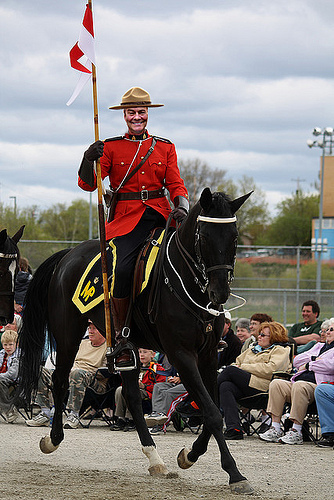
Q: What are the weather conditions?
A: It is overcast.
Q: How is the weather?
A: It is overcast.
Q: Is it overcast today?
A: Yes, it is overcast.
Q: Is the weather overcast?
A: Yes, it is overcast.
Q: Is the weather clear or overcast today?
A: It is overcast.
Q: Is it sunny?
A: No, it is overcast.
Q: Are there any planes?
A: No, there are no planes.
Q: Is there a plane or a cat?
A: No, there are no airplanes or cats.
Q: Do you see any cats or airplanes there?
A: No, there are no airplanes or cats.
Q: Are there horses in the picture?
A: Yes, there is a horse.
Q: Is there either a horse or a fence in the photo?
A: Yes, there is a horse.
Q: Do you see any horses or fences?
A: Yes, there is a horse.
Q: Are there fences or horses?
A: Yes, there is a horse.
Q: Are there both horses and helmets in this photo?
A: No, there is a horse but no helmets.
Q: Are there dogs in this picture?
A: No, there are no dogs.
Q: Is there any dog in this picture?
A: No, there are no dogs.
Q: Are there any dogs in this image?
A: No, there are no dogs.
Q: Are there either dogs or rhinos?
A: No, there are no dogs or rhinos.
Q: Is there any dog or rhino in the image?
A: No, there are no dogs or rhinos.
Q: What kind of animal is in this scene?
A: The animal is a horse.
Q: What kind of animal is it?
A: The animal is a horse.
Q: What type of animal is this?
A: This is a horse.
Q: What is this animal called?
A: This is a horse.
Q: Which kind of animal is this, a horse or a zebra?
A: This is a horse.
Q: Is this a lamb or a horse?
A: This is a horse.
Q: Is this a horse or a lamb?
A: This is a horse.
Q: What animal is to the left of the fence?
A: The animal is a horse.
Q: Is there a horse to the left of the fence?
A: Yes, there is a horse to the left of the fence.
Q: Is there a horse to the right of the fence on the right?
A: No, the horse is to the left of the fence.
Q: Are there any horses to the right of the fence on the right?
A: No, the horse is to the left of the fence.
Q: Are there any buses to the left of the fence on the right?
A: No, there is a horse to the left of the fence.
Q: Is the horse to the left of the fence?
A: Yes, the horse is to the left of the fence.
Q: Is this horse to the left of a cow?
A: No, the horse is to the left of the fence.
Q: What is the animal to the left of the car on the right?
A: The animal is a horse.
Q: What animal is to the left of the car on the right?
A: The animal is a horse.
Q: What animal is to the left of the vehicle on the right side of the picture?
A: The animal is a horse.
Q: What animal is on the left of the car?
A: The animal is a horse.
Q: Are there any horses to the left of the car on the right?
A: Yes, there is a horse to the left of the car.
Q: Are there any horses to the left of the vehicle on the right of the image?
A: Yes, there is a horse to the left of the car.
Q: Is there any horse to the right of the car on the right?
A: No, the horse is to the left of the car.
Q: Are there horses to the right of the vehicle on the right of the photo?
A: No, the horse is to the left of the car.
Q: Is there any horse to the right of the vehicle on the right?
A: No, the horse is to the left of the car.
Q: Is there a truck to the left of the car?
A: No, there is a horse to the left of the car.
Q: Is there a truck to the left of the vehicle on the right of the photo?
A: No, there is a horse to the left of the car.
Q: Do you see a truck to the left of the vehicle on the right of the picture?
A: No, there is a horse to the left of the car.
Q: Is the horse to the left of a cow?
A: No, the horse is to the left of the car.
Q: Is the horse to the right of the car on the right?
A: No, the horse is to the left of the car.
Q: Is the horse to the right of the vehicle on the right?
A: No, the horse is to the left of the car.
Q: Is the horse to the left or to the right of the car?
A: The horse is to the left of the car.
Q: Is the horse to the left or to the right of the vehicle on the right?
A: The horse is to the left of the car.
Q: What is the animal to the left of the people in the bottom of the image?
A: The animal is a horse.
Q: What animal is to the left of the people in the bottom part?
A: The animal is a horse.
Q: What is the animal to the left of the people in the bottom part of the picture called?
A: The animal is a horse.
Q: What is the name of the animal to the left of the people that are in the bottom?
A: The animal is a horse.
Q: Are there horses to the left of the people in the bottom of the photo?
A: Yes, there is a horse to the left of the people.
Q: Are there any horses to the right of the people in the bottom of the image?
A: No, the horse is to the left of the people.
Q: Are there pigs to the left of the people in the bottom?
A: No, there is a horse to the left of the people.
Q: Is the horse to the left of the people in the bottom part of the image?
A: Yes, the horse is to the left of the people.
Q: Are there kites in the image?
A: No, there are no kites.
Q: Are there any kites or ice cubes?
A: No, there are no kites or ice cubes.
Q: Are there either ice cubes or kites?
A: No, there are no kites or ice cubes.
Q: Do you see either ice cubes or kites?
A: No, there are no kites or ice cubes.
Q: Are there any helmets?
A: No, there are no helmets.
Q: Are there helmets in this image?
A: No, there are no helmets.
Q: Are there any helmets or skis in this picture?
A: No, there are no helmets or skis.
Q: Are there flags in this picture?
A: Yes, there is a flag.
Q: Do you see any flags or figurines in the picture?
A: Yes, there is a flag.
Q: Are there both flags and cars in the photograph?
A: Yes, there are both a flag and a car.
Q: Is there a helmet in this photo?
A: No, there are no helmets.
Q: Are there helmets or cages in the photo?
A: No, there are no helmets or cages.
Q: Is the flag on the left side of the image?
A: Yes, the flag is on the left of the image.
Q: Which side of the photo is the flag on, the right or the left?
A: The flag is on the left of the image.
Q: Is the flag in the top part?
A: Yes, the flag is in the top of the image.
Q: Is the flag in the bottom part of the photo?
A: No, the flag is in the top of the image.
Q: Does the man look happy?
A: Yes, the man is happy.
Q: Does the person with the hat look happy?
A: Yes, the man is happy.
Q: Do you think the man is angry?
A: No, the man is happy.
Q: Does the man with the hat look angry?
A: No, the man is happy.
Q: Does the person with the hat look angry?
A: No, the man is happy.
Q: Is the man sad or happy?
A: The man is happy.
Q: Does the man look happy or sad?
A: The man is happy.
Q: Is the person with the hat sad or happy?
A: The man is happy.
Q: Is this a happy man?
A: Yes, this is a happy man.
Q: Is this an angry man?
A: No, this is a happy man.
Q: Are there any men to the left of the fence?
A: Yes, there is a man to the left of the fence.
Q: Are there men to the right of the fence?
A: No, the man is to the left of the fence.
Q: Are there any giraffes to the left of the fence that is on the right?
A: No, there is a man to the left of the fence.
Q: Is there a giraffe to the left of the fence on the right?
A: No, there is a man to the left of the fence.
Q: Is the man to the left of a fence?
A: Yes, the man is to the left of a fence.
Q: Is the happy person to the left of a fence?
A: Yes, the man is to the left of a fence.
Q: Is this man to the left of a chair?
A: No, the man is to the left of a fence.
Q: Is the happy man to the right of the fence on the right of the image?
A: No, the man is to the left of the fence.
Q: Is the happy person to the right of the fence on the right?
A: No, the man is to the left of the fence.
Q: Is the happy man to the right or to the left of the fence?
A: The man is to the left of the fence.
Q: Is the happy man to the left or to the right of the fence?
A: The man is to the left of the fence.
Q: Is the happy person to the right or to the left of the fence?
A: The man is to the left of the fence.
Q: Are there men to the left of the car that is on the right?
A: Yes, there is a man to the left of the car.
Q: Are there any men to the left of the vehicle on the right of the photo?
A: Yes, there is a man to the left of the car.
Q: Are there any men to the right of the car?
A: No, the man is to the left of the car.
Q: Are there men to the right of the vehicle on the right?
A: No, the man is to the left of the car.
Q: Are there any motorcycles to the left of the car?
A: No, there is a man to the left of the car.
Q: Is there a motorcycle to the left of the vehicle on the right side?
A: No, there is a man to the left of the car.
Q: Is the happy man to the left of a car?
A: Yes, the man is to the left of a car.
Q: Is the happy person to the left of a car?
A: Yes, the man is to the left of a car.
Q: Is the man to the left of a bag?
A: No, the man is to the left of a car.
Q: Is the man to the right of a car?
A: No, the man is to the left of a car.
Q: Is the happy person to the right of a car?
A: No, the man is to the left of a car.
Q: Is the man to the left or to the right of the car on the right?
A: The man is to the left of the car.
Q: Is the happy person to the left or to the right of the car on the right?
A: The man is to the left of the car.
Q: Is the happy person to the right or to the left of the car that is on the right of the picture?
A: The man is to the left of the car.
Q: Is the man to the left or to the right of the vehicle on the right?
A: The man is to the left of the car.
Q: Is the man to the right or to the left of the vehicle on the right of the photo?
A: The man is to the left of the car.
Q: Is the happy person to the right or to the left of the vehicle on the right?
A: The man is to the left of the car.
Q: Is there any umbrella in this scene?
A: No, there are no umbrellas.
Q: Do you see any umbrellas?
A: No, there are no umbrellas.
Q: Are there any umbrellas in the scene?
A: No, there are no umbrellas.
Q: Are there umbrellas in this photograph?
A: No, there are no umbrellas.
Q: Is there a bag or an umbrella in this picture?
A: No, there are no umbrellas or bags.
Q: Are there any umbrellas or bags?
A: No, there are no umbrellas or bags.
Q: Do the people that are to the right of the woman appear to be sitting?
A: Yes, the people are sitting.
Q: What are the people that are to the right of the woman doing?
A: The people are sitting.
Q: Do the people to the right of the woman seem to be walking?
A: No, the people are sitting.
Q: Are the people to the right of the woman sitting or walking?
A: The people are sitting.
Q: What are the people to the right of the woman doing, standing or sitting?
A: The people are sitting.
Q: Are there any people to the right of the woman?
A: Yes, there are people to the right of the woman.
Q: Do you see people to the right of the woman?
A: Yes, there are people to the right of the woman.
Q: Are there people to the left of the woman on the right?
A: No, the people are to the right of the woman.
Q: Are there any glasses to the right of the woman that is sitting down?
A: No, there are people to the right of the woman.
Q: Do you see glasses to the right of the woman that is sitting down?
A: No, there are people to the right of the woman.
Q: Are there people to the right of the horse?
A: Yes, there are people to the right of the horse.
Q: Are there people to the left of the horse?
A: No, the people are to the right of the horse.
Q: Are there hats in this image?
A: Yes, there is a hat.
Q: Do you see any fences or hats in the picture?
A: Yes, there is a hat.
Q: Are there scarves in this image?
A: No, there are no scarves.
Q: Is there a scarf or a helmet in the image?
A: No, there are no scarves or helmets.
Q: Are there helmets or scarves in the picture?
A: No, there are no scarves or helmets.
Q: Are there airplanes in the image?
A: No, there are no airplanes.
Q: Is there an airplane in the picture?
A: No, there are no airplanes.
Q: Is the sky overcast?
A: Yes, the sky is overcast.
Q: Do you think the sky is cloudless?
A: No, the sky is overcast.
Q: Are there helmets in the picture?
A: No, there are no helmets.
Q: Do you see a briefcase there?
A: No, there are no briefcases.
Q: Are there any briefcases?
A: No, there are no briefcases.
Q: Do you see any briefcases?
A: No, there are no briefcases.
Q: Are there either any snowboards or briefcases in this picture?
A: No, there are no briefcases or snowboards.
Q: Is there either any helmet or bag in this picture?
A: No, there are no helmets or bags.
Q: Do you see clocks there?
A: No, there are no clocks.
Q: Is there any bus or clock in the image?
A: No, there are no clocks or buses.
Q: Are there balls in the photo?
A: No, there are no balls.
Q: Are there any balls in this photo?
A: No, there are no balls.